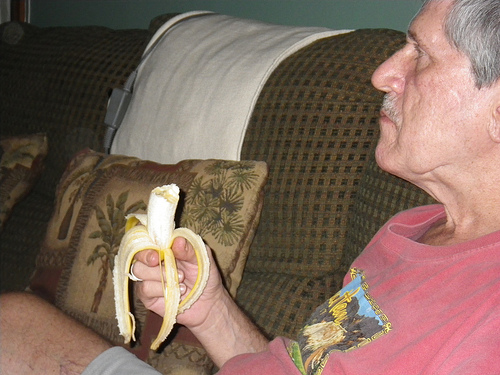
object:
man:
[0, 0, 500, 374]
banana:
[112, 182, 211, 351]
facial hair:
[380, 93, 404, 132]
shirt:
[208, 203, 500, 374]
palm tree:
[89, 187, 153, 318]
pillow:
[27, 146, 267, 374]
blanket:
[100, 8, 356, 165]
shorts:
[73, 346, 174, 375]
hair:
[440, 0, 500, 90]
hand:
[131, 236, 221, 326]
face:
[370, 0, 498, 174]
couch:
[1, 13, 441, 373]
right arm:
[195, 289, 272, 368]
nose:
[370, 46, 407, 96]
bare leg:
[0, 292, 114, 374]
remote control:
[102, 70, 137, 154]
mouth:
[378, 106, 398, 126]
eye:
[413, 45, 429, 61]